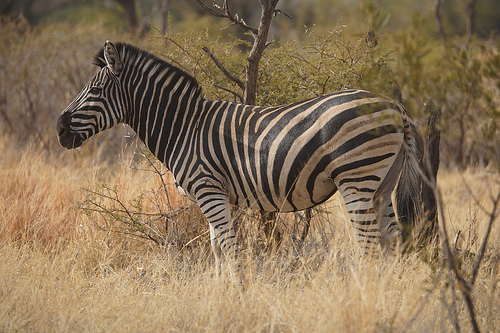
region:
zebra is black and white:
[36, 30, 496, 272]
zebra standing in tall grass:
[38, 35, 463, 300]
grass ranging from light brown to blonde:
[21, 176, 221, 316]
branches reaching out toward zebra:
[75, 160, 185, 257]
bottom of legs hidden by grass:
[175, 245, 420, 325]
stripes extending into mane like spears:
[125, 41, 205, 168]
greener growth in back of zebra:
[275, 30, 476, 125]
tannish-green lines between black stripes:
[295, 85, 405, 196]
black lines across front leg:
[182, 196, 247, 268]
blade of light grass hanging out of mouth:
[55, 115, 81, 190]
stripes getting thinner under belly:
[280, 175, 330, 220]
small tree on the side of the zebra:
[190, 35, 497, 107]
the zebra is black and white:
[132, 80, 417, 195]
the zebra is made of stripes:
[85, 59, 453, 229]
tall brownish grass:
[25, 162, 215, 303]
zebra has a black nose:
[35, 27, 165, 177]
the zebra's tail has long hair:
[372, 100, 457, 231]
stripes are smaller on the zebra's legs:
[185, 185, 261, 253]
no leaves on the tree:
[201, 0, 322, 110]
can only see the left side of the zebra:
[63, 46, 463, 221]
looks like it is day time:
[96, 3, 476, 32]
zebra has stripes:
[57, 40, 422, 299]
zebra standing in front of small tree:
[55, 2, 416, 291]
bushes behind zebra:
[2, 0, 499, 293]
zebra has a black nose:
[56, 40, 418, 291]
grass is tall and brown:
[2, 130, 499, 331]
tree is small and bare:
[192, 0, 301, 251]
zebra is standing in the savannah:
[0, 0, 499, 332]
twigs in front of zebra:
[354, 51, 499, 332]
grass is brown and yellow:
[46, 220, 295, 328]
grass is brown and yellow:
[4, 155, 155, 308]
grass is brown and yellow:
[119, 225, 394, 330]